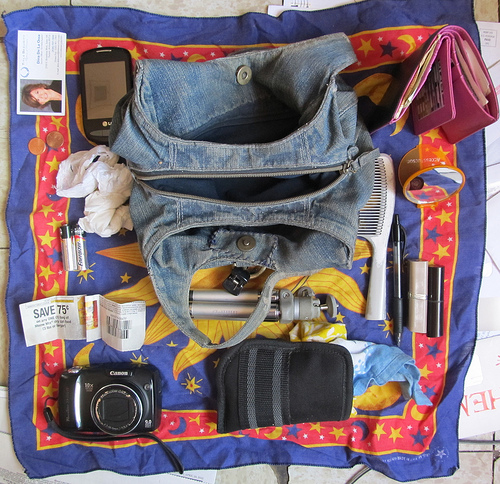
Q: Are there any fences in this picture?
A: No, there are no fences.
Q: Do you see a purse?
A: Yes, there is a purse.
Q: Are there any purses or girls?
A: Yes, there is a purse.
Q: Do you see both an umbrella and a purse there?
A: No, there is a purse but no umbrellas.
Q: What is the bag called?
A: The bag is a purse.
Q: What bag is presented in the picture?
A: The bag is a purse.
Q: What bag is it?
A: The bag is a purse.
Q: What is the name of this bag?
A: This is a purse.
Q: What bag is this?
A: This is a purse.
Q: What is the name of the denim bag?
A: The bag is a purse.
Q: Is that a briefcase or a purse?
A: That is a purse.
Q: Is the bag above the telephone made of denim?
A: Yes, the purse is made of denim.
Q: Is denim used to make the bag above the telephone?
A: Yes, the purse is made of denim.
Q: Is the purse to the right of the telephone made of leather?
A: No, the purse is made of denim.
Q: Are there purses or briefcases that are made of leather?
A: No, there is a purse but it is made of denim.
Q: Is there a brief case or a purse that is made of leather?
A: No, there is a purse but it is made of denim.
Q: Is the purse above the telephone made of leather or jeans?
A: The purse is made of jeans.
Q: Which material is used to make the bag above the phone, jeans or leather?
A: The purse is made of jeans.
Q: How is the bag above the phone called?
A: The bag is a purse.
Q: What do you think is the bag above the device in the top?
A: The bag is a purse.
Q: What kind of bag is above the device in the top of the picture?
A: The bag is a purse.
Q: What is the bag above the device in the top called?
A: The bag is a purse.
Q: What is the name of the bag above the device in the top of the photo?
A: The bag is a purse.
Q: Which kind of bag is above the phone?
A: The bag is a purse.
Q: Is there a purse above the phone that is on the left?
A: Yes, there is a purse above the phone.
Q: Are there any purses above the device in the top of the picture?
A: Yes, there is a purse above the phone.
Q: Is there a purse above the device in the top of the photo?
A: Yes, there is a purse above the phone.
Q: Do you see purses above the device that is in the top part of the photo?
A: Yes, there is a purse above the phone.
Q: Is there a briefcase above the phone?
A: No, there is a purse above the phone.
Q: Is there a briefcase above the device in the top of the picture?
A: No, there is a purse above the phone.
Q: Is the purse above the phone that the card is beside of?
A: Yes, the purse is above the telephone.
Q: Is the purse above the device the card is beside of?
A: Yes, the purse is above the telephone.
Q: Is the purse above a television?
A: No, the purse is above the telephone.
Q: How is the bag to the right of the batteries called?
A: The bag is a purse.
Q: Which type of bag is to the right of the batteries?
A: The bag is a purse.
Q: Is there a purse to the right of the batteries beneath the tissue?
A: Yes, there is a purse to the right of the batteries.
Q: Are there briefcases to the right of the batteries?
A: No, there is a purse to the right of the batteries.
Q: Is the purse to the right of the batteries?
A: Yes, the purse is to the right of the batteries.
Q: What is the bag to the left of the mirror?
A: The bag is a purse.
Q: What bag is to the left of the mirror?
A: The bag is a purse.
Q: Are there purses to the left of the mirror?
A: Yes, there is a purse to the left of the mirror.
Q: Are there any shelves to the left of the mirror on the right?
A: No, there is a purse to the left of the mirror.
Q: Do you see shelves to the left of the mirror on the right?
A: No, there is a purse to the left of the mirror.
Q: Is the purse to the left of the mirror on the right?
A: Yes, the purse is to the left of the mirror.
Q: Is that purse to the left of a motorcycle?
A: No, the purse is to the left of the mirror.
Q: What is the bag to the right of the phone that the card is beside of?
A: The bag is a purse.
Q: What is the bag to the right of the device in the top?
A: The bag is a purse.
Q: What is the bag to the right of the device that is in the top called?
A: The bag is a purse.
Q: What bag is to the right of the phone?
A: The bag is a purse.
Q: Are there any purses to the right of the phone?
A: Yes, there is a purse to the right of the phone.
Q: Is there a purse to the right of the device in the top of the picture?
A: Yes, there is a purse to the right of the phone.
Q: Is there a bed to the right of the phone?
A: No, there is a purse to the right of the phone.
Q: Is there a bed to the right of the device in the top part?
A: No, there is a purse to the right of the phone.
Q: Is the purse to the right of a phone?
A: Yes, the purse is to the right of a phone.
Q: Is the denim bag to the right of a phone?
A: Yes, the purse is to the right of a phone.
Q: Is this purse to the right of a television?
A: No, the purse is to the right of a phone.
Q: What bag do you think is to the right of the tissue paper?
A: The bag is a purse.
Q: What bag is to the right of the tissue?
A: The bag is a purse.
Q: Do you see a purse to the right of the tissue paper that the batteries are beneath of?
A: Yes, there is a purse to the right of the tissue.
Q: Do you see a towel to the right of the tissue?
A: No, there is a purse to the right of the tissue.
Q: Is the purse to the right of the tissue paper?
A: Yes, the purse is to the right of the tissue paper.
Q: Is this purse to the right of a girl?
A: No, the purse is to the right of the tissue paper.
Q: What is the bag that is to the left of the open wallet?
A: The bag is a purse.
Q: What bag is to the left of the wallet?
A: The bag is a purse.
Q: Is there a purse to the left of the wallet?
A: Yes, there is a purse to the left of the wallet.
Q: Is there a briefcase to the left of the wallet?
A: No, there is a purse to the left of the wallet.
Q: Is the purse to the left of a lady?
A: No, the purse is to the left of a wallet.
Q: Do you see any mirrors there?
A: Yes, there is a mirror.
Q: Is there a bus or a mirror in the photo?
A: Yes, there is a mirror.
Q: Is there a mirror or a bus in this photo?
A: Yes, there is a mirror.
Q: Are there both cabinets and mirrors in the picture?
A: No, there is a mirror but no cabinets.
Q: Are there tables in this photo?
A: No, there are no tables.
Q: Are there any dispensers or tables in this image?
A: No, there are no tables or dispensers.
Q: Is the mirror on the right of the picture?
A: Yes, the mirror is on the right of the image.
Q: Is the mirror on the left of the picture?
A: No, the mirror is on the right of the image.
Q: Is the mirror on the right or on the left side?
A: The mirror is on the right of the image.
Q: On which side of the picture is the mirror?
A: The mirror is on the right of the image.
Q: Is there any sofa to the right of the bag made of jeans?
A: No, there is a mirror to the right of the purse.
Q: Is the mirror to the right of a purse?
A: Yes, the mirror is to the right of a purse.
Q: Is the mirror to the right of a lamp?
A: No, the mirror is to the right of a purse.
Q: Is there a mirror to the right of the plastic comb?
A: Yes, there is a mirror to the right of the comb.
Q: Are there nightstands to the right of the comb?
A: No, there is a mirror to the right of the comb.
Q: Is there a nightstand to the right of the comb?
A: No, there is a mirror to the right of the comb.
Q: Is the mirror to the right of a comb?
A: Yes, the mirror is to the right of a comb.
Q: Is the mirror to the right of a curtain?
A: No, the mirror is to the right of a comb.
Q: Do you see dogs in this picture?
A: No, there are no dogs.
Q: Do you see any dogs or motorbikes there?
A: No, there are no dogs or motorbikes.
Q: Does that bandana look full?
A: Yes, the bandana is full.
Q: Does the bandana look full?
A: Yes, the bandana is full.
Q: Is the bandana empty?
A: No, the bandana is full.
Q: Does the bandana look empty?
A: No, the bandana is full.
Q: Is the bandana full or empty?
A: The bandana is full.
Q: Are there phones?
A: Yes, there is a phone.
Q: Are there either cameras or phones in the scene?
A: Yes, there is a phone.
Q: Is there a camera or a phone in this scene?
A: Yes, there is a phone.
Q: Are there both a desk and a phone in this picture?
A: No, there is a phone but no desks.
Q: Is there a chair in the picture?
A: No, there are no chairs.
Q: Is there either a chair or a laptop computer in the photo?
A: No, there are no chairs or laptops.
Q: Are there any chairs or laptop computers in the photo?
A: No, there are no chairs or laptop computers.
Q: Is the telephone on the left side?
A: Yes, the telephone is on the left of the image.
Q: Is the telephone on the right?
A: No, the telephone is on the left of the image.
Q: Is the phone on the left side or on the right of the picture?
A: The phone is on the left of the image.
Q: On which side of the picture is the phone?
A: The phone is on the left of the image.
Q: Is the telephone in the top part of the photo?
A: Yes, the telephone is in the top of the image.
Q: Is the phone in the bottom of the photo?
A: No, the phone is in the top of the image.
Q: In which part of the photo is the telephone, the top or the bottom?
A: The telephone is in the top of the image.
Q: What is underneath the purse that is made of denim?
A: The telephone is underneath the purse.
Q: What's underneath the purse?
A: The telephone is underneath the purse.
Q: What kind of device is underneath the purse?
A: The device is a phone.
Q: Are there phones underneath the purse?
A: Yes, there is a phone underneath the purse.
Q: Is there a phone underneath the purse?
A: Yes, there is a phone underneath the purse.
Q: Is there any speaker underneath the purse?
A: No, there is a phone underneath the purse.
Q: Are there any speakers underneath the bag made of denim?
A: No, there is a phone underneath the purse.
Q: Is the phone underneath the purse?
A: Yes, the phone is underneath the purse.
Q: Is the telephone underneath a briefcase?
A: No, the telephone is underneath the purse.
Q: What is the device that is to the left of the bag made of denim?
A: The device is a phone.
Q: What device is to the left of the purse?
A: The device is a phone.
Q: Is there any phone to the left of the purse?
A: Yes, there is a phone to the left of the purse.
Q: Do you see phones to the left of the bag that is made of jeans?
A: Yes, there is a phone to the left of the purse.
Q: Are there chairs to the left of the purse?
A: No, there is a phone to the left of the purse.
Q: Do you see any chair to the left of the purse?
A: No, there is a phone to the left of the purse.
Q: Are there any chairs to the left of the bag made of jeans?
A: No, there is a phone to the left of the purse.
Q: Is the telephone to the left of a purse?
A: Yes, the telephone is to the left of a purse.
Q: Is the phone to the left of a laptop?
A: No, the phone is to the left of a purse.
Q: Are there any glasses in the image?
A: No, there are no glasses.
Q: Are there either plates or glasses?
A: No, there are no glasses or plates.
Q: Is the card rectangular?
A: Yes, the card is rectangular.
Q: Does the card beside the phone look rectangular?
A: Yes, the card is rectangular.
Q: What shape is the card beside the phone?
A: The card is rectangular.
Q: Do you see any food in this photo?
A: No, there is no food.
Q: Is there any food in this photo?
A: No, there is no food.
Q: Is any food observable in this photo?
A: No, there is no food.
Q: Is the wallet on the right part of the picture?
A: Yes, the wallet is on the right of the image.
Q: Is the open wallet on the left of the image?
A: No, the wallet is on the right of the image.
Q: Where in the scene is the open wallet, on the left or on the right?
A: The wallet is on the right of the image.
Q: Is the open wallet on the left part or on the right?
A: The wallet is on the right of the image.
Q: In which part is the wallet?
A: The wallet is on the right of the image.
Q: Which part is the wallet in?
A: The wallet is on the right of the image.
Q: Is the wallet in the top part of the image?
A: Yes, the wallet is in the top of the image.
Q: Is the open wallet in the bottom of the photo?
A: No, the wallet is in the top of the image.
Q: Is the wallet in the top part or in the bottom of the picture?
A: The wallet is in the top of the image.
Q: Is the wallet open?
A: Yes, the wallet is open.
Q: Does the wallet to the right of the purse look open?
A: Yes, the wallet is open.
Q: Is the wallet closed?
A: No, the wallet is open.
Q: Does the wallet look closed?
A: No, the wallet is open.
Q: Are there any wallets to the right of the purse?
A: Yes, there is a wallet to the right of the purse.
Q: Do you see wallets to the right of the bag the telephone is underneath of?
A: Yes, there is a wallet to the right of the purse.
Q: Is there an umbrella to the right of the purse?
A: No, there is a wallet to the right of the purse.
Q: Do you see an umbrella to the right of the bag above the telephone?
A: No, there is a wallet to the right of the purse.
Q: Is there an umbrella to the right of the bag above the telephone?
A: No, there is a wallet to the right of the purse.